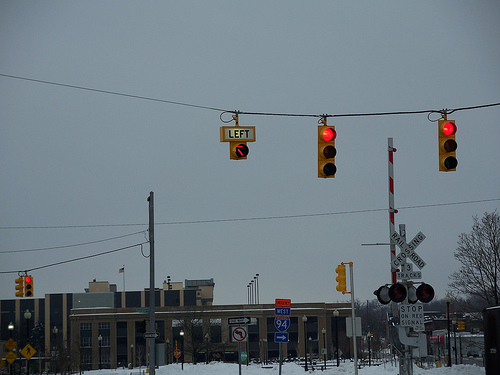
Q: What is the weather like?
A: Overcast.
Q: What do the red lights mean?
A: Stop.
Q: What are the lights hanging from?
A: Wire.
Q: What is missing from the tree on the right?
A: Leaves.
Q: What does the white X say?
A: Railroad crossing.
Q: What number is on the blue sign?
A: 94.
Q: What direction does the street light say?
A: Left.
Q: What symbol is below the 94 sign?
A: Arrow.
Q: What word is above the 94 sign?
A: West.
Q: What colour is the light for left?
A: Red.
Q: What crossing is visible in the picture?
A: Railroad crossing.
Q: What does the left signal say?
A: Left.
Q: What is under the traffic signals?
A: A railroad crossing.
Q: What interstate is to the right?
A: I 94.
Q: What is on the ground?
A: Snow.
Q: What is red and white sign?
A: No left.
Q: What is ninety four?
A: Highway.